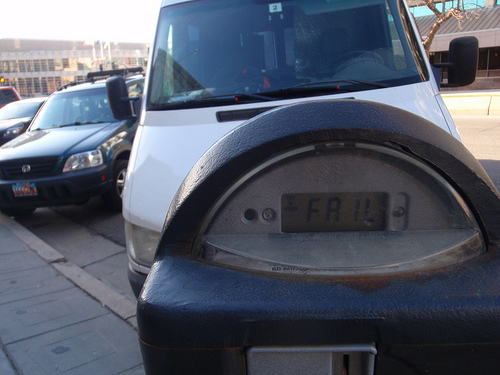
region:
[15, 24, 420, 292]
the cars are parked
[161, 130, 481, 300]
top of the meter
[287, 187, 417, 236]
screen on the meter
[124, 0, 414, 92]
windshield of the van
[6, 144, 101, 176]
front of the car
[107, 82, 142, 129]
mirror on the van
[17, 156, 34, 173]
logo on the car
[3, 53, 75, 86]
windows on the building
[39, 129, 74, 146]
reflection on the hood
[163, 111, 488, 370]
black parking meter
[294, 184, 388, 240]
black letters on display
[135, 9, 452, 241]
white van behind meter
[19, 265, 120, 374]
sidewalk is dark grey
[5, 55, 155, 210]
blue car near van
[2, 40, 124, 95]
large building on left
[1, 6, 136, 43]
grey and bright sky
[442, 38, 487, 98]
large black rear view mirrors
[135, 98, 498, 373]
A black parking meter.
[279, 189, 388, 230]
Screen on a parking meter.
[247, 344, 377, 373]
A coin slot on a meter.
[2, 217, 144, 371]
Part of a sidewalk.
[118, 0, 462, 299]
A van parked at the curb.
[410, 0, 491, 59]
Part of a tree.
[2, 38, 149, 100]
A building behind the cars.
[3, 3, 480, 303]
Cars parked at the curb.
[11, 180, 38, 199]
A cars license plate.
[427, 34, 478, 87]
A vans side mirror.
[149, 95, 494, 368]
black parking meter on sidewalk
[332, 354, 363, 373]
entry for the coins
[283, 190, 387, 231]
display screen on meter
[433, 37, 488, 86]
side view mirror on left side of van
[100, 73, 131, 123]
sideview mirror on right side of van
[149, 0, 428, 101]
windshield on the white van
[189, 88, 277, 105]
windshield wiper on windshield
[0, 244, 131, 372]
cement pavement on the ground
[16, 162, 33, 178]
symbol of the car company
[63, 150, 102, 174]
headlight on the truck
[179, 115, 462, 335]
black meter near van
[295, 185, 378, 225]
black letters on timer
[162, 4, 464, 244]
white van behind meter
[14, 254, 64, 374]
dark grey sidewalk near van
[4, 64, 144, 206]
blue truck near van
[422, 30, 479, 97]
black driver's side mirror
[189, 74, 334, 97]
black windshield wipers on van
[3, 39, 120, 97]
brown building in distance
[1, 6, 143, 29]
grey and bright sky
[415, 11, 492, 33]
brown roof on building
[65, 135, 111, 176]
light on a car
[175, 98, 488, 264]
parking meter on sidewalk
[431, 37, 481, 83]
mirror on a van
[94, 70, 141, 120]
mirror on a van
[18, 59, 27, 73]
A window on a building.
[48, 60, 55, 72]
A window on a building.